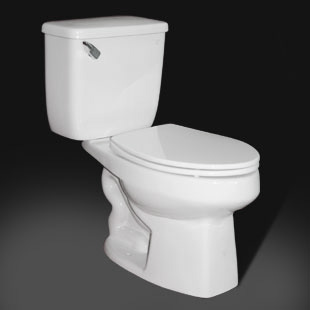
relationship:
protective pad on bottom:
[110, 123, 260, 170] [81, 123, 260, 188]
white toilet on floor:
[27, 8, 278, 293] [19, 215, 297, 302]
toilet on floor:
[38, 32, 261, 285] [14, 109, 308, 308]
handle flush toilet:
[84, 40, 99, 59] [44, 17, 261, 298]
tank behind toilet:
[34, 8, 171, 145] [26, 23, 245, 209]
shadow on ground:
[232, 174, 300, 284] [65, 214, 298, 308]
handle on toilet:
[83, 40, 101, 59] [50, 21, 248, 190]